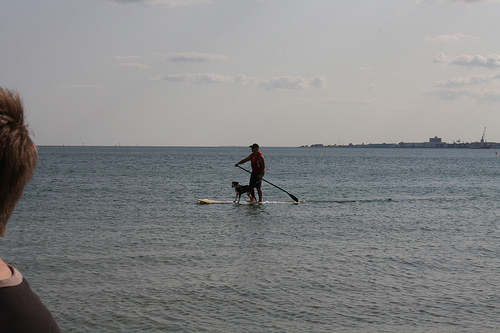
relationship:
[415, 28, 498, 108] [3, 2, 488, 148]
cloud in sky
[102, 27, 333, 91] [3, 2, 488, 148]
cloud in sky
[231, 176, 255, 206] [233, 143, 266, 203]
dog standing with person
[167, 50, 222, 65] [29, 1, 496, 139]
cloud in sky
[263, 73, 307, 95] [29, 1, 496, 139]
cloud in sky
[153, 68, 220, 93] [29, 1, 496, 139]
cloud in sky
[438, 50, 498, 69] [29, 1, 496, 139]
cloud in sky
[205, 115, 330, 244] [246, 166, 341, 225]
person using paddle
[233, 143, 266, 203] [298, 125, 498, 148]
person by city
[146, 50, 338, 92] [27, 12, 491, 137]
clouds in sky